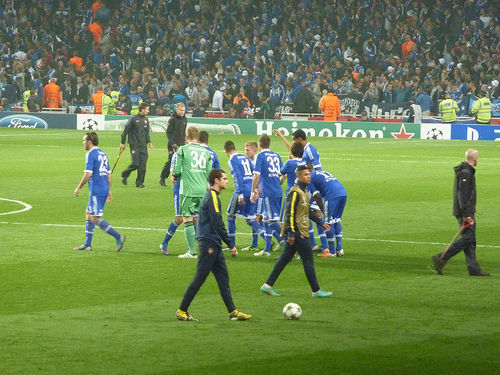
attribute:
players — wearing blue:
[83, 108, 354, 323]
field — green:
[3, 139, 497, 374]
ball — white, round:
[283, 304, 303, 319]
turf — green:
[8, 127, 78, 240]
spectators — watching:
[6, 1, 497, 108]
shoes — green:
[258, 286, 337, 300]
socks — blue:
[77, 224, 119, 242]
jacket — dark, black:
[450, 158, 472, 218]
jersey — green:
[173, 144, 212, 195]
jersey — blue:
[85, 151, 113, 198]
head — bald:
[466, 149, 481, 168]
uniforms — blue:
[227, 144, 352, 261]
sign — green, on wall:
[111, 117, 421, 141]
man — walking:
[437, 139, 487, 282]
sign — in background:
[1, 114, 75, 132]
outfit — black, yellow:
[270, 190, 323, 292]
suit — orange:
[316, 97, 342, 119]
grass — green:
[6, 128, 495, 372]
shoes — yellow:
[173, 311, 257, 321]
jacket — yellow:
[100, 94, 114, 113]